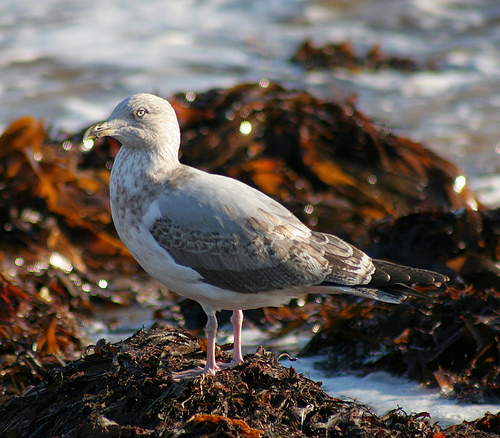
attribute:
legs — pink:
[171, 305, 245, 382]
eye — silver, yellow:
[136, 109, 146, 117]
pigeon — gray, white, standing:
[80, 91, 455, 384]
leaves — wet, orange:
[180, 83, 470, 169]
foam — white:
[287, 361, 498, 422]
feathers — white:
[111, 165, 451, 320]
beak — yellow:
[87, 121, 117, 142]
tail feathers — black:
[305, 226, 451, 307]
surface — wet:
[5, 96, 499, 433]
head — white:
[88, 91, 180, 168]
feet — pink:
[166, 356, 245, 384]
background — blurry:
[1, 1, 492, 121]